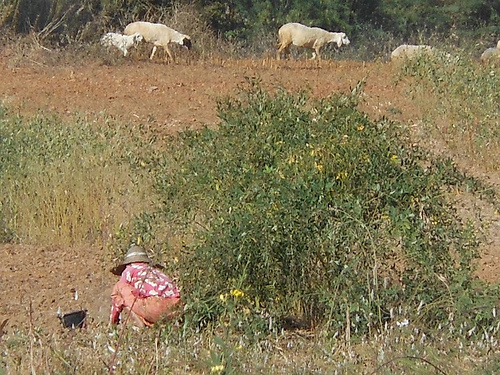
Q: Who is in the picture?
A: A woman.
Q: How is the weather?
A: Sunny.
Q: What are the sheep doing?
A: Walking.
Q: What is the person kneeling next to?
A: A bush.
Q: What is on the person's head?
A: Hat.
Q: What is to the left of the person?
A: Bucket.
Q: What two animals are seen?
A: Goat and dog.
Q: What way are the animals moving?
A: Right.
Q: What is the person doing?
A: Working.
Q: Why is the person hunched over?
A: Working.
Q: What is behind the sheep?
A: Trees.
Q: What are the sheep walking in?
A: Grass.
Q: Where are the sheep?
A: In the grass.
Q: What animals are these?
A: Sheep.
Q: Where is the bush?
A: By the farmer.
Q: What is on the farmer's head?
A: A hat.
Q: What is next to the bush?
A: A crouching man.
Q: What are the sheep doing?
A: Walking.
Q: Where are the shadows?
A: On the ground.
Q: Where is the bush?
A: Bottom right.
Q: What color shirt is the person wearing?
A: Red.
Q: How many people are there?
A: One.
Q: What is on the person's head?
A: A hat.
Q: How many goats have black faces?
A: One.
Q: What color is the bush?
A: Green.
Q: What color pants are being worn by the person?
A: Brown.